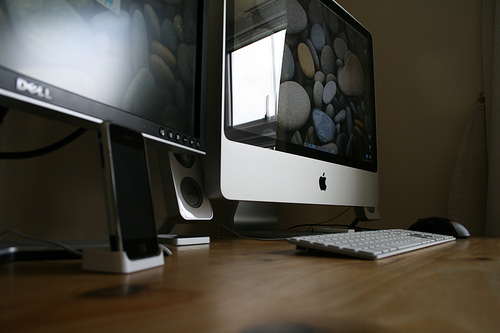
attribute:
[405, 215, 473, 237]
mouse — black, silver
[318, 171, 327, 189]
apple logo — black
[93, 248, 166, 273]
dock — white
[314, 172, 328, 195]
logo — black on silver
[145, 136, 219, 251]
speaker — black, silver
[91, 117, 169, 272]
phone — black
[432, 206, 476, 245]
mouse — black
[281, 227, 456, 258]
keyboard — white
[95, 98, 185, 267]
iphone — apple, black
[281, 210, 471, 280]
computer keyboard — white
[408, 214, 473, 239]
mouse — silver, black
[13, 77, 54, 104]
lettering — silver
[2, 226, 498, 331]
desk — light brown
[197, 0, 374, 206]
computer screen — apple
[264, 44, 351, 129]
rocks — assorted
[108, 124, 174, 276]
computer speaker — silver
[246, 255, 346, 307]
desk — tan, brown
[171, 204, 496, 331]
desk — wood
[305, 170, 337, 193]
logo — black 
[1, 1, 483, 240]
walls — white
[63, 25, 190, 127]
screen — dell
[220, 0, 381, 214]
monitor — flat screen